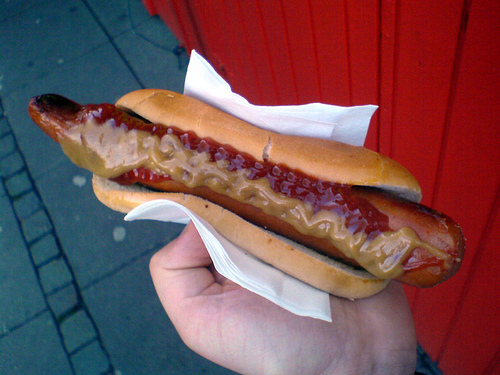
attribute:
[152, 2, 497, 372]
wall — red, wooden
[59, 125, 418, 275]
mustard — topping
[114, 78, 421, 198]
bun — hotdog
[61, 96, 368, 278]
hot dog — grilled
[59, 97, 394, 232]
ketchup — topping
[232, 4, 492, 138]
wall — red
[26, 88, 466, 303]
hot dog — held, grilled, big, well cooked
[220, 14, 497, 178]
wall — red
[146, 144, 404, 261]
hot dog — delicious 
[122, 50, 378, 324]
napkin — white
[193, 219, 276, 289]
napkin — white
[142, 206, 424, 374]
hand — person's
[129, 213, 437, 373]
hand — someone's